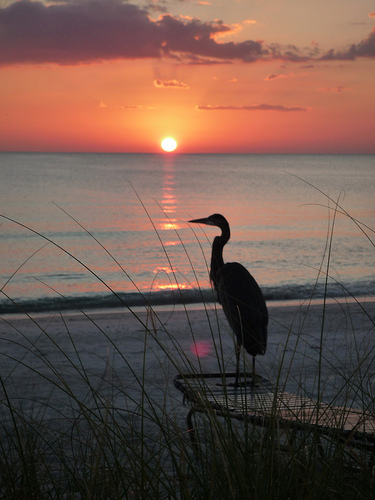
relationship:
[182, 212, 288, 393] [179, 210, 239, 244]
bird has head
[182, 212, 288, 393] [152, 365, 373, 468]
bird on chair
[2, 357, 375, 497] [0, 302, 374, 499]
grass on beach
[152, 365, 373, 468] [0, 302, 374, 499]
chair on beach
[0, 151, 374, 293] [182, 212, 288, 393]
water near bird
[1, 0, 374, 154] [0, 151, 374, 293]
sky above water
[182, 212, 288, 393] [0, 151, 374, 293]
bird near water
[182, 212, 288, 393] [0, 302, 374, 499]
bird on beach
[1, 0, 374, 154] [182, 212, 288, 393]
sky above bird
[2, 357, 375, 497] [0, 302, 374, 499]
grass near beach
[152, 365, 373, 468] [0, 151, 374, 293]
chair by water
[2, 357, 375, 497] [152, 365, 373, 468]
grass by chair